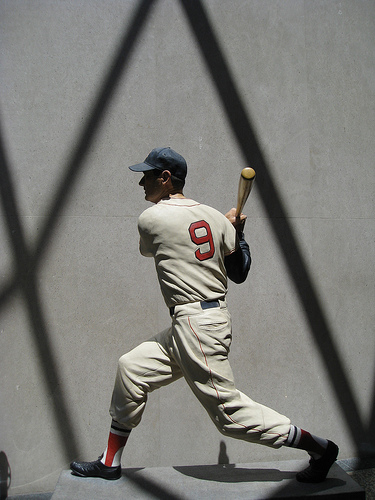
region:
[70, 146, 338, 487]
baseball player in white uniform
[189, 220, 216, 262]
red nine number in the back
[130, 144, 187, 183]
black cap of baseball player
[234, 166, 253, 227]
light brown wooden baseball bat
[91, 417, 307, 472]
red blue and white socks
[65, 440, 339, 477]
pair of black shoes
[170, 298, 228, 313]
gray belt in white buckles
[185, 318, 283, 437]
red line in white pants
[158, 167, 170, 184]
small left ear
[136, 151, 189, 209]
side face of baseball player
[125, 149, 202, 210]
Baseball player wearing blue hat.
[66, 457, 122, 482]
Black baseball cleat.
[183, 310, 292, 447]
Red stripe going down side of pant leg.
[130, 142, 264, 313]
Baseball player holding bat.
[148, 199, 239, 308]
Number nine on baseball shirt.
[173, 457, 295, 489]
Shadow of player's leg.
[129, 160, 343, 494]
Baseball player standing with left leg back.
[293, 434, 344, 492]
Left heel of player is lifted.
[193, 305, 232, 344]
Back pocket of pants.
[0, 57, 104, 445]
Shadow of fence in background.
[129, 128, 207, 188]
man wearing a hat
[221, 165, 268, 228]
man holding a bat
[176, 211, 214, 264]
red number on man's shirt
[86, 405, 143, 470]
sock is red and white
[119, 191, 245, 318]
man's shirt is white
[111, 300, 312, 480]
man's pants are white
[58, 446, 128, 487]
man's shoe is black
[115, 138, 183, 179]
man's hat is black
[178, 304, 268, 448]
red stripe on man's pants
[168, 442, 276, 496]
shadow of man on ground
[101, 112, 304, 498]
a sculpture holding a bat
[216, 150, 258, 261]
the bat is brown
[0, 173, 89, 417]
shadows on the wall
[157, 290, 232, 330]
the belt is blue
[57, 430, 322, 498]
the shoes are black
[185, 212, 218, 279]
the number is 9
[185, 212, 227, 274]
the number is red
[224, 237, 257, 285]
the sleeves are black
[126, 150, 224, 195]
the cap is gray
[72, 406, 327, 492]
the socks are red and white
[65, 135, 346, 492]
a small baseball player figurine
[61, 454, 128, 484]
a baseball player's shoe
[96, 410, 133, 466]
a baseball player's sock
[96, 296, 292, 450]
a baseball player's pair of pants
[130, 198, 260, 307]
a jersey with the number nine on it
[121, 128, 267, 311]
a baseball player holding a bat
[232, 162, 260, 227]
a baseball bat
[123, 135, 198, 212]
a baseball player with a blue cap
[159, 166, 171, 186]
a human ear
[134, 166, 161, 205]
a human face